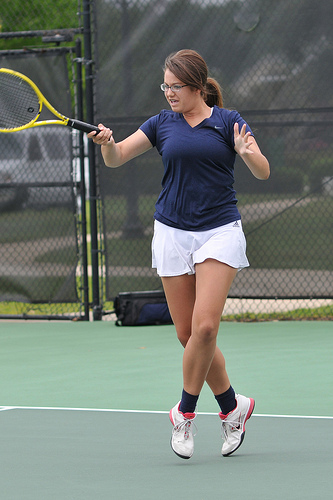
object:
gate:
[0, 28, 96, 322]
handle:
[66, 117, 111, 142]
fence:
[0, 0, 333, 322]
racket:
[0, 68, 111, 143]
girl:
[87, 45, 272, 461]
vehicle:
[0, 117, 96, 213]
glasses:
[160, 82, 189, 93]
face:
[163, 64, 199, 113]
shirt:
[137, 103, 256, 233]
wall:
[91, 1, 333, 301]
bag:
[111, 289, 176, 327]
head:
[162, 46, 210, 115]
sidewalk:
[48, 295, 333, 322]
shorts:
[150, 217, 251, 279]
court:
[0, 0, 333, 500]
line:
[0, 405, 333, 420]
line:
[0, 407, 12, 410]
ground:
[0, 317, 333, 500]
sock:
[214, 384, 238, 415]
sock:
[178, 386, 200, 415]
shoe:
[168, 400, 197, 461]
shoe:
[218, 392, 256, 458]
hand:
[87, 123, 114, 147]